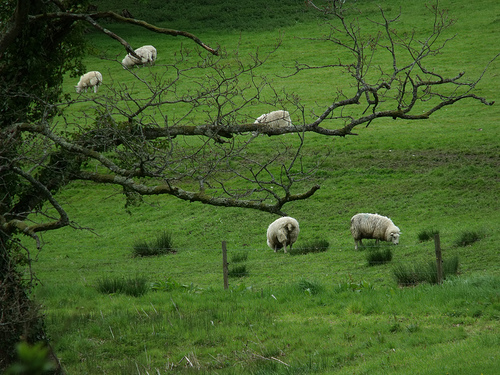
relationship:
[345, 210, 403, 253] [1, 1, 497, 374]
sheep eats meadow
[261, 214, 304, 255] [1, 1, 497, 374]
sheep eats meadow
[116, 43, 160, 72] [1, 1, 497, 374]
sheep eats meadow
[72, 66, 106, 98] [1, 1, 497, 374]
sheep eats meadow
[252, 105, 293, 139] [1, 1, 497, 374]
sheep eats meadow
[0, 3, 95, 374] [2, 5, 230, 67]
tree has branch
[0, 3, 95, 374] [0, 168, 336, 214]
tree has branch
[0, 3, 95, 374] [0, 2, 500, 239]
tree has branch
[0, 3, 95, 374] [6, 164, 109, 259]
tree has branch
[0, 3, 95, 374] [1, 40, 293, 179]
tree has branch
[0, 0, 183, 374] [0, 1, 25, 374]
leaves nearest trunk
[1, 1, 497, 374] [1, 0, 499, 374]
meadow on prairie [?]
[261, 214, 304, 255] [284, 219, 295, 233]
sheep has tail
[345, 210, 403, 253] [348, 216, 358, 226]
sheep has tail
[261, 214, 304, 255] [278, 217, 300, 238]
sheep has butt end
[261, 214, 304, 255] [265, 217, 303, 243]
sheep has wool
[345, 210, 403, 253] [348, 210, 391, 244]
sheep has wool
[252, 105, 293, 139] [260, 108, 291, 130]
sheep has wool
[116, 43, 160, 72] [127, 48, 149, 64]
sheep has wool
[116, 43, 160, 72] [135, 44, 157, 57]
sheep has wool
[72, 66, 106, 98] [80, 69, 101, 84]
sheep has wool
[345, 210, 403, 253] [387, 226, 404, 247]
sheep has head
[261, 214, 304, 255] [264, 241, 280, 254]
sheep has head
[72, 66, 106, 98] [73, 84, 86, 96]
sheep has head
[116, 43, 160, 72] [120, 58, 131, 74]
sheep has head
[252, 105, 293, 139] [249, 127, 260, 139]
sheep has head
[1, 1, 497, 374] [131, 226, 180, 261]
meadow in patch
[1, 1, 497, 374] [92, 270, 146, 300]
meadow in patch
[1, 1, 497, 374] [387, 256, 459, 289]
meadow in patch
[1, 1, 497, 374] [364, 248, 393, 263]
meadow in patch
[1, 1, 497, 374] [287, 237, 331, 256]
meadow in patch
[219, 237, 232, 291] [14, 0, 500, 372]
post in ground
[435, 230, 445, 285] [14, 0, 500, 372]
poles in ground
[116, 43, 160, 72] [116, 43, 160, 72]
sheep has sheep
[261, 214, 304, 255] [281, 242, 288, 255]
sheep has leg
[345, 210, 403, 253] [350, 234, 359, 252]
sheep has leg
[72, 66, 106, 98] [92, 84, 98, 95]
sheep has leg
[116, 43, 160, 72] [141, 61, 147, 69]
sheep has leg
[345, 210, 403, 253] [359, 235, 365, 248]
sheep has leg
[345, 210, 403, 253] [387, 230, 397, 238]
sheep has ear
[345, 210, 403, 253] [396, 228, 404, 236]
sheep has ear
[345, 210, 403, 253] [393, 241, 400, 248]
sheep has nose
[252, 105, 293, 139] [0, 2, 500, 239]
sheep behind branch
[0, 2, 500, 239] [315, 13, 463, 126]
branch has branchlet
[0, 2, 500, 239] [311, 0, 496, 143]
branch has branchlet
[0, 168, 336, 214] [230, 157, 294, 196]
branch has branchlet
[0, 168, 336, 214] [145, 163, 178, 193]
branch has branchlet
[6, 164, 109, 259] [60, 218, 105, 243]
branch has branchlet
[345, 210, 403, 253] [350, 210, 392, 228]
sheep has back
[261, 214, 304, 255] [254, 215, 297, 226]
sheep has back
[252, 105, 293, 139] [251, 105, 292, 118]
sheep has back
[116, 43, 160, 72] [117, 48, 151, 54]
sheep has back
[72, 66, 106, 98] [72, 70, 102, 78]
sheep has back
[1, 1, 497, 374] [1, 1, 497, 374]
meadow in meadow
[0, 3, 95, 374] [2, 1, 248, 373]
tree on left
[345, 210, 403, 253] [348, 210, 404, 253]
sheep has side view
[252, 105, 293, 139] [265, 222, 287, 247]
sheep has side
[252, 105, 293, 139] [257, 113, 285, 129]
sheep has side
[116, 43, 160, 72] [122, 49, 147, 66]
sheep has side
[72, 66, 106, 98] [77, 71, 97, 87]
sheep has side